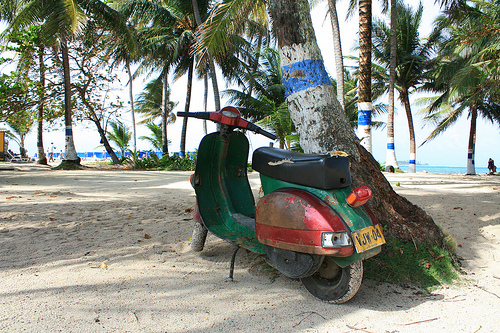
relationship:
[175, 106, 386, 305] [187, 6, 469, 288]
bike parked next to tree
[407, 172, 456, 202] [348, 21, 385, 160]
grass near tree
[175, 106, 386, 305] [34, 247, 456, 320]
bike on sand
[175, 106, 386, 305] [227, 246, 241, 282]
bike has center stand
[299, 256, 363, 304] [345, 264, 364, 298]
tire has dirt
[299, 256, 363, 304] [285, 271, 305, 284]
tire has edge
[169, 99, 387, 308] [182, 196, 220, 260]
bike has wheel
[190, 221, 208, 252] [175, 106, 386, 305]
tire of bike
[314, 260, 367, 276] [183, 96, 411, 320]
exhaust of scooter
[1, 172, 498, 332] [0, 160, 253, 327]
sand on beach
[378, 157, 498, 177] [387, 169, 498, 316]
water near sand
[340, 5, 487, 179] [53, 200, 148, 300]
trees in sand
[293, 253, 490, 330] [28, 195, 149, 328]
twigs in sand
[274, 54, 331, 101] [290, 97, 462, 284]
paint on tree trunk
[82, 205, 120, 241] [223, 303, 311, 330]
part on shade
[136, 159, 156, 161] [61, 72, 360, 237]
part of a grass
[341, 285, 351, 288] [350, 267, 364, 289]
part of a wheell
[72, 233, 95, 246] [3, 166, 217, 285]
part of a shade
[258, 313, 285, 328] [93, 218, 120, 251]
part of a shade